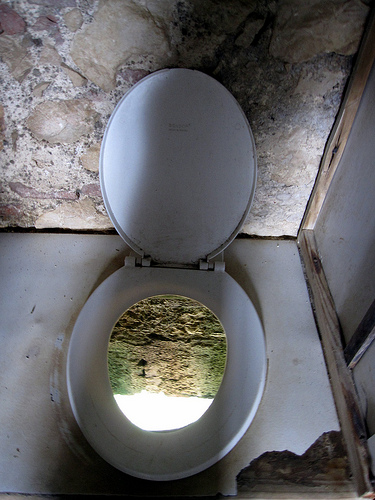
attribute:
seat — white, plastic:
[77, 339, 229, 450]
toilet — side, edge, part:
[67, 144, 260, 450]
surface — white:
[24, 320, 71, 413]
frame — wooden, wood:
[299, 222, 326, 277]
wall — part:
[97, 8, 168, 43]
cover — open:
[101, 281, 211, 422]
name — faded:
[144, 116, 195, 140]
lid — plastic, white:
[104, 68, 241, 265]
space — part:
[7, 230, 54, 252]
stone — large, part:
[73, 210, 116, 234]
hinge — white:
[152, 252, 211, 308]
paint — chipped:
[47, 367, 86, 426]